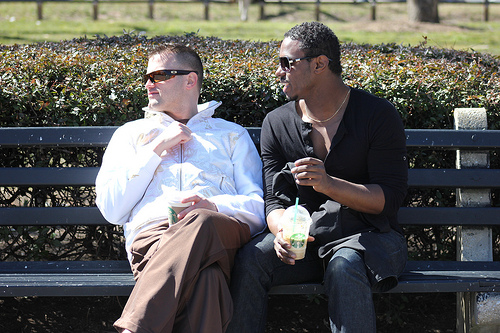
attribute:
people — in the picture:
[96, 20, 407, 332]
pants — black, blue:
[232, 226, 406, 332]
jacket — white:
[95, 101, 266, 252]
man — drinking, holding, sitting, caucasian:
[95, 46, 267, 332]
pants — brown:
[109, 209, 254, 332]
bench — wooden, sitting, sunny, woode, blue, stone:
[1, 106, 499, 331]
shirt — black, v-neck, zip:
[262, 90, 410, 235]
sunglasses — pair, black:
[277, 54, 317, 74]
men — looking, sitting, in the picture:
[96, 23, 410, 332]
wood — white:
[467, 268, 499, 295]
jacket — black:
[275, 163, 413, 293]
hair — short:
[148, 44, 204, 90]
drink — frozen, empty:
[165, 198, 195, 227]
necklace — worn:
[302, 88, 349, 123]